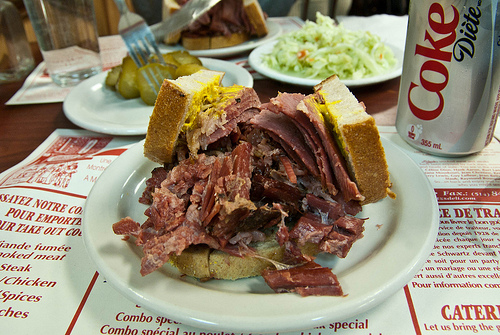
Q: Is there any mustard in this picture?
A: Yes, there is mustard.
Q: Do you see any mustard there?
A: Yes, there is mustard.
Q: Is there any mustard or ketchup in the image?
A: Yes, there is mustard.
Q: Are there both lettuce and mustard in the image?
A: Yes, there are both mustard and lettuce.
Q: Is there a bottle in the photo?
A: No, there are no bottles.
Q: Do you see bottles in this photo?
A: No, there are no bottles.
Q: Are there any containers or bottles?
A: No, there are no bottles or containers.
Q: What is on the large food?
A: The mustard is on the food.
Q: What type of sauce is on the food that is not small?
A: The sauce is mustard.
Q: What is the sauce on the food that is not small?
A: The sauce is mustard.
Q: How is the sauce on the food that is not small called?
A: The sauce is mustard.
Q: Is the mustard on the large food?
A: Yes, the mustard is on the food.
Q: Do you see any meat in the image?
A: Yes, there is meat.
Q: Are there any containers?
A: No, there are no containers.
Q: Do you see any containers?
A: No, there are no containers.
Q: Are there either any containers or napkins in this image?
A: No, there are no containers or napkins.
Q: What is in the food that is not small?
A: The meat is in the food.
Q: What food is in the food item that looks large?
A: The food is meat.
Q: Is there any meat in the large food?
A: Yes, there is meat in the food.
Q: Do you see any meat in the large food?
A: Yes, there is meat in the food.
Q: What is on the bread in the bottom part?
A: The meat is on the bread.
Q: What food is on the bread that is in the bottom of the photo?
A: The food is meat.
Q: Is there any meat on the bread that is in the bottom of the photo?
A: Yes, there is meat on the bread.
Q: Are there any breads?
A: Yes, there is a bread.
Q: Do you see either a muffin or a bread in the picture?
A: Yes, there is a bread.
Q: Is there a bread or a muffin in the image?
A: Yes, there is a bread.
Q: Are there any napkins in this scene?
A: No, there are no napkins.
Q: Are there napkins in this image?
A: No, there are no napkins.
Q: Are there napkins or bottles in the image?
A: No, there are no napkins or bottles.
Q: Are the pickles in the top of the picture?
A: Yes, the pickles are in the top of the image.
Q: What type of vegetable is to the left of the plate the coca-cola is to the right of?
A: The vegetables are pickles.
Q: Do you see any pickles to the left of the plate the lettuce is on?
A: Yes, there are pickles to the left of the plate.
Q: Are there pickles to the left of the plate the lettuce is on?
A: Yes, there are pickles to the left of the plate.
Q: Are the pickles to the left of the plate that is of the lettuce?
A: Yes, the pickles are to the left of the plate.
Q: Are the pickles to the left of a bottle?
A: No, the pickles are to the left of the plate.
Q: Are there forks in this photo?
A: Yes, there is a fork.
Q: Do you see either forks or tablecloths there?
A: Yes, there is a fork.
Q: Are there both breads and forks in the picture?
A: Yes, there are both a fork and a bread.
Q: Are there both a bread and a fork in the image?
A: Yes, there are both a fork and a bread.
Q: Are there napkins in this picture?
A: No, there are no napkins.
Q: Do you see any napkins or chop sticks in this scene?
A: No, there are no napkins or chop sticks.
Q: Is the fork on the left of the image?
A: Yes, the fork is on the left of the image.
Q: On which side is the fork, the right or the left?
A: The fork is on the left of the image.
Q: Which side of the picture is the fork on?
A: The fork is on the left of the image.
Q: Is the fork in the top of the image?
A: Yes, the fork is in the top of the image.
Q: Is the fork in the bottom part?
A: No, the fork is in the top of the image.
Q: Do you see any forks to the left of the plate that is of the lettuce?
A: Yes, there is a fork to the left of the plate.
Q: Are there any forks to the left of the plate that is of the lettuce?
A: Yes, there is a fork to the left of the plate.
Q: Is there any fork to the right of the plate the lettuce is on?
A: No, the fork is to the left of the plate.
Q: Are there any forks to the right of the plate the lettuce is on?
A: No, the fork is to the left of the plate.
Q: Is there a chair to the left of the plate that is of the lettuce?
A: No, there is a fork to the left of the plate.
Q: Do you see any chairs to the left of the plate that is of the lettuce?
A: No, there is a fork to the left of the plate.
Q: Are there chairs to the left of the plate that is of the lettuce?
A: No, there is a fork to the left of the plate.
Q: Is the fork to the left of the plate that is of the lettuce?
A: Yes, the fork is to the left of the plate.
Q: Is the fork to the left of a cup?
A: No, the fork is to the left of the plate.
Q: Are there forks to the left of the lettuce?
A: Yes, there is a fork to the left of the lettuce.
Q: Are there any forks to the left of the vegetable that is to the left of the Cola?
A: Yes, there is a fork to the left of the lettuce.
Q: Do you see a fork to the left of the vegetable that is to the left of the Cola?
A: Yes, there is a fork to the left of the lettuce.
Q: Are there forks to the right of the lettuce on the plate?
A: No, the fork is to the left of the lettuce.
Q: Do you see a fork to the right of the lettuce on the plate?
A: No, the fork is to the left of the lettuce.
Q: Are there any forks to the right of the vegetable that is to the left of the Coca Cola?
A: No, the fork is to the left of the lettuce.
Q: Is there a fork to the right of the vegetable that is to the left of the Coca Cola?
A: No, the fork is to the left of the lettuce.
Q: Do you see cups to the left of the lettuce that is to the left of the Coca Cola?
A: No, there is a fork to the left of the lettuce.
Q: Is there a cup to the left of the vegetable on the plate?
A: No, there is a fork to the left of the lettuce.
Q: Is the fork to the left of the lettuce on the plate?
A: Yes, the fork is to the left of the lettuce.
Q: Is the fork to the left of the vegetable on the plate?
A: Yes, the fork is to the left of the lettuce.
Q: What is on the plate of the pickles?
A: The fork is on the plate.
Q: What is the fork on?
A: The fork is on the plate.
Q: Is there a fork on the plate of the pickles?
A: Yes, there is a fork on the plate.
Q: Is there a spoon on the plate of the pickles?
A: No, there is a fork on the plate.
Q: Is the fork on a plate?
A: Yes, the fork is on a plate.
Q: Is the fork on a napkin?
A: No, the fork is on a plate.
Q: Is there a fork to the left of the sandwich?
A: Yes, there is a fork to the left of the sandwich.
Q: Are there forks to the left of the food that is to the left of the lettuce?
A: Yes, there is a fork to the left of the sandwich.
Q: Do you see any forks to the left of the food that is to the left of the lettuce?
A: Yes, there is a fork to the left of the sandwich.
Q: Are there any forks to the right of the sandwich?
A: No, the fork is to the left of the sandwich.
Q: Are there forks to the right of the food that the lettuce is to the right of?
A: No, the fork is to the left of the sandwich.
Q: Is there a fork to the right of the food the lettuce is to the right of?
A: No, the fork is to the left of the sandwich.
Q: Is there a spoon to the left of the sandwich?
A: No, there is a fork to the left of the sandwich.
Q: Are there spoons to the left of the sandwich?
A: No, there is a fork to the left of the sandwich.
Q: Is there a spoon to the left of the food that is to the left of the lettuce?
A: No, there is a fork to the left of the sandwich.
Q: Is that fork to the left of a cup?
A: No, the fork is to the left of the sandwich.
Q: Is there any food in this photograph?
A: Yes, there is food.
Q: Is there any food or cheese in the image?
A: Yes, there is food.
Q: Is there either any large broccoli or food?
A: Yes, there is large food.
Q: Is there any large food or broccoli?
A: Yes, there is large food.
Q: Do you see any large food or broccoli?
A: Yes, there is large food.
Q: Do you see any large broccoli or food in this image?
A: Yes, there is large food.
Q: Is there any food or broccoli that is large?
A: Yes, the food is large.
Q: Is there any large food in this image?
A: Yes, there is large food.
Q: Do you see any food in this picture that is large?
A: Yes, there is food that is large.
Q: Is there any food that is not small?
A: Yes, there is large food.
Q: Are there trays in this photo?
A: No, there are no trays.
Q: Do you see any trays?
A: No, there are no trays.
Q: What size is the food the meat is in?
A: The food is large.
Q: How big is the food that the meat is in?
A: The food is large.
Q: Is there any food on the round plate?
A: Yes, there is food on the plate.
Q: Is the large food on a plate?
A: Yes, the food is on a plate.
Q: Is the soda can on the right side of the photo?
A: Yes, the soda can is on the right of the image.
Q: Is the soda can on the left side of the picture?
A: No, the soda can is on the right of the image.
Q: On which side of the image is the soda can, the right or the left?
A: The soda can is on the right of the image.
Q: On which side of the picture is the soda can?
A: The soda can is on the right of the image.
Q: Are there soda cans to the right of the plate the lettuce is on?
A: Yes, there is a soda can to the right of the plate.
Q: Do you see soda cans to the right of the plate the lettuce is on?
A: Yes, there is a soda can to the right of the plate.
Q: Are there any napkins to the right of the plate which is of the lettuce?
A: No, there is a soda can to the right of the plate.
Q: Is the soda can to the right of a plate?
A: Yes, the soda can is to the right of a plate.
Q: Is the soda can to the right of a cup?
A: No, the soda can is to the right of a plate.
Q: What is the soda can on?
A: The soda can is on the table.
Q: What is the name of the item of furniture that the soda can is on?
A: The piece of furniture is a table.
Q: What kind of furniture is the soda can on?
A: The soda can is on the table.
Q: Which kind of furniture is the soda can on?
A: The soda can is on the table.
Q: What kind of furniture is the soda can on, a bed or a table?
A: The soda can is on a table.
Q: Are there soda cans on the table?
A: Yes, there is a soda can on the table.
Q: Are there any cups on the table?
A: No, there is a soda can on the table.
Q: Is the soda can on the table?
A: Yes, the soda can is on the table.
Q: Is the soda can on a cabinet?
A: No, the soda can is on the table.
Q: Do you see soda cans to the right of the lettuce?
A: Yes, there is a soda can to the right of the lettuce.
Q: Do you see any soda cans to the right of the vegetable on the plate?
A: Yes, there is a soda can to the right of the lettuce.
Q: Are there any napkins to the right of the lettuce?
A: No, there is a soda can to the right of the lettuce.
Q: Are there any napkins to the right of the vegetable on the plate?
A: No, there is a soda can to the right of the lettuce.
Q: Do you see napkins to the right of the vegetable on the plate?
A: No, there is a soda can to the right of the lettuce.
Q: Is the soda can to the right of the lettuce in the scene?
A: Yes, the soda can is to the right of the lettuce.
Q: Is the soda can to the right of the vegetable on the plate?
A: Yes, the soda can is to the right of the lettuce.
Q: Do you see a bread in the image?
A: Yes, there is a bread.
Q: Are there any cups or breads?
A: Yes, there is a bread.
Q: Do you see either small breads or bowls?
A: Yes, there is a small bread.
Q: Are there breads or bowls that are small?
A: Yes, the bread is small.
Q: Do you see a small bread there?
A: Yes, there is a small bread.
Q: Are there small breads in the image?
A: Yes, there is a small bread.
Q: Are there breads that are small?
A: Yes, there is a bread that is small.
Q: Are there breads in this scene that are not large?
A: Yes, there is a small bread.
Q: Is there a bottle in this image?
A: No, there are no bottles.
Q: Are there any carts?
A: No, there are no carts.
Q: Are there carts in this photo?
A: No, there are no carts.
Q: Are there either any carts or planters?
A: No, there are no carts or planters.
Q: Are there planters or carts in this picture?
A: No, there are no carts or planters.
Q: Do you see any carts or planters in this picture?
A: No, there are no carts or planters.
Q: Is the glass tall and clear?
A: Yes, the glass is tall and clear.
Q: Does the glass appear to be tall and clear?
A: Yes, the glass is tall and clear.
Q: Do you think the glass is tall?
A: Yes, the glass is tall.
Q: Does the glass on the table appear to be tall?
A: Yes, the glass is tall.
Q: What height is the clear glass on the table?
A: The glass is tall.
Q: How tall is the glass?
A: The glass is tall.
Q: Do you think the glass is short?
A: No, the glass is tall.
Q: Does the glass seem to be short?
A: No, the glass is tall.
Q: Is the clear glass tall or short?
A: The glass is tall.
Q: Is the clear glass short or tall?
A: The glass is tall.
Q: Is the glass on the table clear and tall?
A: Yes, the glass is clear and tall.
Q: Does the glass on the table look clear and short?
A: No, the glass is clear but tall.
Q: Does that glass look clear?
A: Yes, the glass is clear.